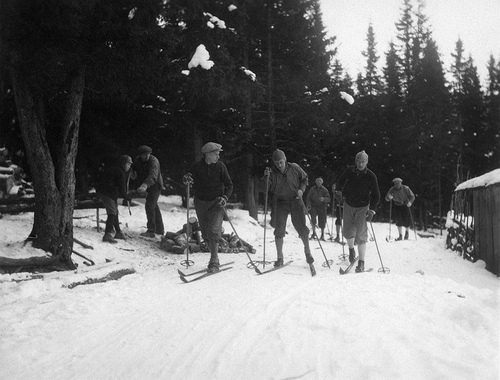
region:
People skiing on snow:
[160, 132, 458, 313]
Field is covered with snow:
[4, 200, 498, 372]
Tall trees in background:
[17, 0, 494, 211]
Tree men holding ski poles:
[173, 131, 400, 292]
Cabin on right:
[438, 152, 498, 293]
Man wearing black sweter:
[330, 144, 398, 289]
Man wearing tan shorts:
[338, 200, 372, 257]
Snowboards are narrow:
[181, 245, 385, 305]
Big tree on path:
[1, 1, 122, 259]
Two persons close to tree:
[85, 138, 166, 270]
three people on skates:
[190, 141, 376, 278]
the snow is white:
[183, 282, 405, 353]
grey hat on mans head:
[203, 142, 224, 154]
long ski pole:
[265, 180, 272, 270]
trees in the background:
[262, 81, 484, 146]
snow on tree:
[178, 22, 221, 75]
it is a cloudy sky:
[336, 6, 498, 41]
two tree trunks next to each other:
[23, 124, 91, 200]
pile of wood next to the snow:
[170, 217, 198, 252]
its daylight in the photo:
[3, 2, 498, 374]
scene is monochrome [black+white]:
[1, 0, 498, 379]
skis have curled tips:
[174, 267, 193, 285]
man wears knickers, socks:
[333, 191, 378, 247]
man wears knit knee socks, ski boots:
[343, 235, 368, 276]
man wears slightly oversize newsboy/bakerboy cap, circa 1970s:
[198, 138, 226, 154]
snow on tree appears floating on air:
[111, 1, 290, 96]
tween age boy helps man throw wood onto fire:
[91, 150, 134, 245]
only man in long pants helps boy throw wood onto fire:
[121, 137, 166, 237]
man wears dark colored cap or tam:
[132, 140, 149, 155]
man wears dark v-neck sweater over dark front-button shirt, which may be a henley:
[179, 154, 236, 212]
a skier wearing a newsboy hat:
[176, 141, 262, 286]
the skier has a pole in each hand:
[173, 140, 263, 282]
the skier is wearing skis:
[175, 140, 260, 285]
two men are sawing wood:
[93, 143, 164, 241]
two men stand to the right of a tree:
[97, 145, 169, 235]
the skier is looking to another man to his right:
[176, 142, 258, 285]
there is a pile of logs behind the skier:
[163, 217, 250, 257]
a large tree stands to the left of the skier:
[0, 1, 80, 271]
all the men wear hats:
[94, 142, 416, 272]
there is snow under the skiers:
[0, 191, 496, 378]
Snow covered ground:
[56, 303, 430, 363]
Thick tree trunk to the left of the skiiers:
[35, 189, 83, 258]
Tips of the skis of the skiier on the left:
[171, 264, 188, 286]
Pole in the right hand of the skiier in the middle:
[258, 182, 270, 269]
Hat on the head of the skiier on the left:
[195, 142, 227, 152]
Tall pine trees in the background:
[368, 21, 435, 101]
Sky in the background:
[338, 6, 484, 34]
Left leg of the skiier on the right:
[352, 210, 367, 246]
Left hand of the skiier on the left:
[213, 196, 232, 211]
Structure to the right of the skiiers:
[441, 180, 498, 249]